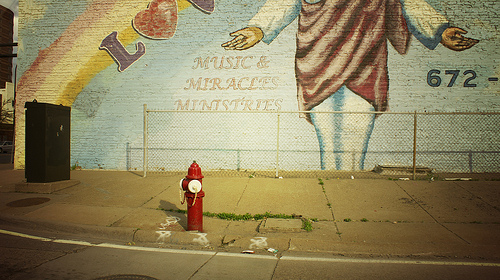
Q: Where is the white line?
A: Beside the sidewalk.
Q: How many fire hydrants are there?
A: One.